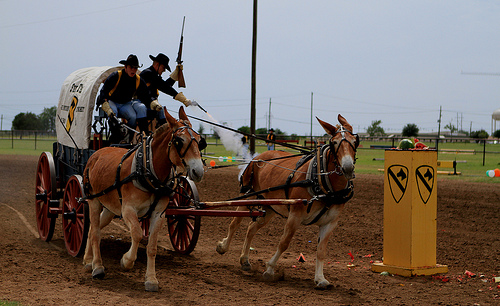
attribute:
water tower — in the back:
[487, 108, 498, 138]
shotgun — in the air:
[158, 20, 215, 138]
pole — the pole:
[238, 1, 293, 157]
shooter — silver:
[182, 97, 209, 115]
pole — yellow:
[371, 145, 450, 277]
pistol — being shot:
[182, 99, 205, 115]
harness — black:
[127, 133, 182, 203]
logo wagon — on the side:
[46, 89, 83, 139]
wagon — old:
[26, 58, 311, 270]